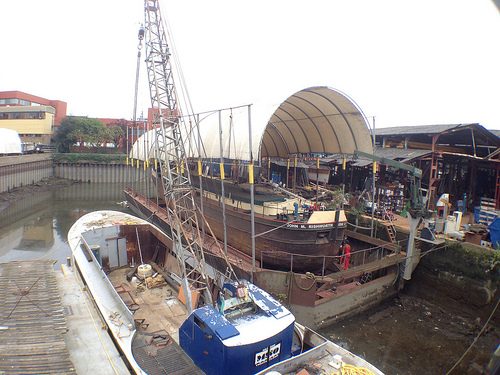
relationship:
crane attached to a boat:
[131, 1, 228, 307] [66, 209, 384, 374]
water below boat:
[0, 176, 499, 374] [124, 169, 348, 273]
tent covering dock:
[128, 82, 377, 163] [129, 185, 431, 330]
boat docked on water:
[124, 169, 348, 273] [0, 176, 499, 374]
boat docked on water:
[66, 209, 384, 374] [0, 176, 499, 374]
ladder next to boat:
[382, 222, 401, 247] [124, 169, 348, 273]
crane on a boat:
[131, 1, 228, 307] [66, 209, 384, 374]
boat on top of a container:
[124, 169, 348, 273] [123, 181, 410, 328]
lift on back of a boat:
[357, 150, 422, 282] [124, 169, 348, 273]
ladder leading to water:
[382, 222, 401, 247] [0, 176, 499, 374]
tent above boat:
[128, 82, 377, 163] [124, 169, 348, 273]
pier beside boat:
[1, 259, 82, 375] [66, 209, 384, 374]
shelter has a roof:
[371, 122, 499, 224] [366, 122, 499, 165]